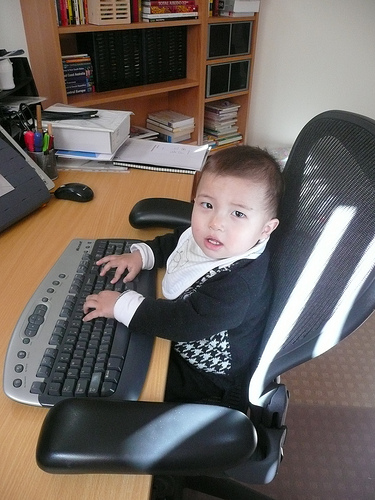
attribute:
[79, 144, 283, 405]
boy — sitting, asian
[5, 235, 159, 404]
keyboard — grey, computer, silver, black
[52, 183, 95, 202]
mouse — black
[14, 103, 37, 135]
scissors — black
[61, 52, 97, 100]
books — stacked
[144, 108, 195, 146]
books — stacked, satcked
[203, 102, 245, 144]
books — stacked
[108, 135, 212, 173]
folder — white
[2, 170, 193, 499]
desk — wood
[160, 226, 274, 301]
bib — white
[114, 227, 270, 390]
shirt — checked, black, white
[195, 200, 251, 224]
eyes — dark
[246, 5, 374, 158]
wall — white